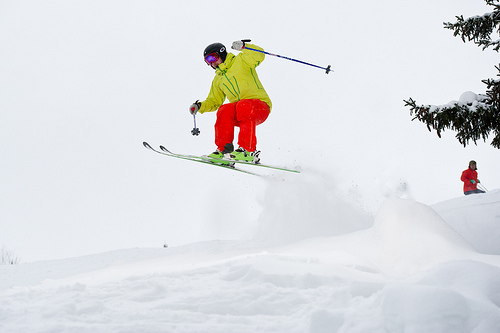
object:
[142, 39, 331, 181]
man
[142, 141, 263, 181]
skis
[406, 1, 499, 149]
snow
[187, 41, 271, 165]
girls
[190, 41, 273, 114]
jacket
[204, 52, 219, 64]
goggles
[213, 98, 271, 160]
orange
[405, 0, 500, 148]
tree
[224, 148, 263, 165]
boots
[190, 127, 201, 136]
prongs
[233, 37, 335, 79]
pole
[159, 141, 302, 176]
ski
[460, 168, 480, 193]
jacket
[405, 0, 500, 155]
evergreen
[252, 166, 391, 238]
up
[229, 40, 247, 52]
holding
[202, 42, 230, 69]
black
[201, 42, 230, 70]
head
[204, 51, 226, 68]
face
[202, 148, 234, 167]
neon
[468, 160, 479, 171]
hat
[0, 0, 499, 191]
above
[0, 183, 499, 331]
hill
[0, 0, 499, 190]
grey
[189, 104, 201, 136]
pole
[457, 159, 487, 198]
man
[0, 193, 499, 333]
ground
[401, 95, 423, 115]
tips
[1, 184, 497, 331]
snow